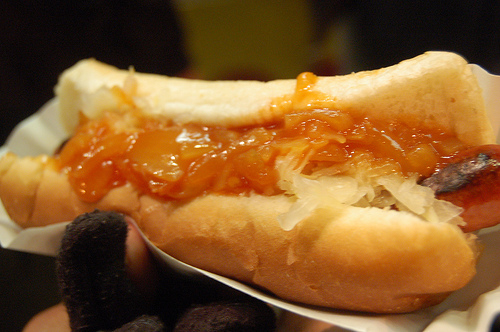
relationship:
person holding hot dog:
[22, 213, 288, 329] [13, 44, 500, 273]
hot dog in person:
[13, 44, 500, 273] [22, 213, 288, 329]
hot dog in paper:
[13, 44, 500, 273] [0, 206, 65, 255]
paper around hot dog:
[0, 206, 65, 255] [13, 44, 500, 273]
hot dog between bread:
[13, 44, 500, 273] [68, 60, 295, 120]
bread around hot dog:
[68, 60, 295, 120] [13, 44, 500, 273]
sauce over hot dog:
[78, 114, 239, 186] [13, 44, 500, 273]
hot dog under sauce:
[13, 44, 500, 273] [78, 114, 239, 186]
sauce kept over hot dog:
[78, 114, 239, 186] [13, 44, 500, 273]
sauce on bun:
[78, 114, 239, 186] [11, 159, 174, 226]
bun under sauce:
[11, 159, 174, 226] [78, 114, 239, 186]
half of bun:
[20, 151, 435, 301] [11, 159, 174, 226]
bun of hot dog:
[11, 159, 174, 226] [13, 44, 500, 273]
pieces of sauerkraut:
[172, 158, 225, 190] [280, 143, 389, 203]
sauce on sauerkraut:
[78, 114, 239, 186] [280, 143, 389, 203]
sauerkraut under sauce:
[280, 143, 389, 203] [78, 114, 239, 186]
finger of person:
[68, 214, 168, 295] [22, 213, 288, 329]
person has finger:
[22, 213, 288, 329] [68, 214, 168, 295]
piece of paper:
[314, 311, 389, 331] [0, 206, 65, 255]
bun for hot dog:
[11, 159, 174, 226] [13, 44, 500, 273]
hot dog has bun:
[13, 44, 500, 273] [11, 159, 174, 226]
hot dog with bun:
[13, 44, 500, 273] [11, 159, 174, 226]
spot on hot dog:
[431, 151, 491, 192] [13, 44, 500, 273]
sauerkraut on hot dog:
[280, 143, 389, 203] [13, 44, 500, 273]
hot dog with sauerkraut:
[13, 44, 500, 273] [280, 143, 389, 203]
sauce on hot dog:
[78, 114, 239, 186] [13, 44, 500, 273]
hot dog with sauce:
[13, 44, 500, 273] [78, 114, 239, 186]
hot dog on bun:
[13, 44, 500, 273] [11, 159, 174, 226]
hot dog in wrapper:
[13, 44, 500, 273] [3, 111, 205, 317]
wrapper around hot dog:
[3, 111, 205, 317] [13, 44, 500, 273]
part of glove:
[146, 302, 234, 322] [70, 218, 124, 297]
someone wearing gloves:
[22, 213, 288, 329] [65, 225, 149, 318]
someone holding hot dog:
[22, 213, 288, 329] [13, 44, 500, 273]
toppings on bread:
[77, 106, 393, 208] [68, 60, 295, 120]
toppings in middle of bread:
[77, 106, 393, 208] [68, 60, 295, 120]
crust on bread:
[173, 232, 262, 278] [68, 60, 295, 120]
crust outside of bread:
[173, 232, 262, 278] [68, 60, 295, 120]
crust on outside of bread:
[173, 232, 262, 278] [68, 60, 295, 120]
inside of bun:
[385, 88, 450, 125] [11, 159, 174, 226]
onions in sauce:
[107, 88, 140, 145] [78, 114, 239, 186]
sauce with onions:
[78, 114, 239, 186] [107, 88, 140, 145]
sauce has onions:
[78, 114, 239, 186] [107, 88, 140, 145]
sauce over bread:
[78, 114, 239, 186] [68, 60, 295, 120]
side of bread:
[41, 161, 127, 219] [68, 60, 295, 120]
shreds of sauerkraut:
[372, 178, 451, 213] [280, 143, 389, 203]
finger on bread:
[68, 214, 168, 295] [68, 60, 295, 120]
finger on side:
[68, 214, 168, 295] [41, 161, 127, 219]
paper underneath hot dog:
[0, 206, 65, 255] [13, 44, 500, 273]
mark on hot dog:
[431, 151, 491, 192] [13, 44, 500, 273]